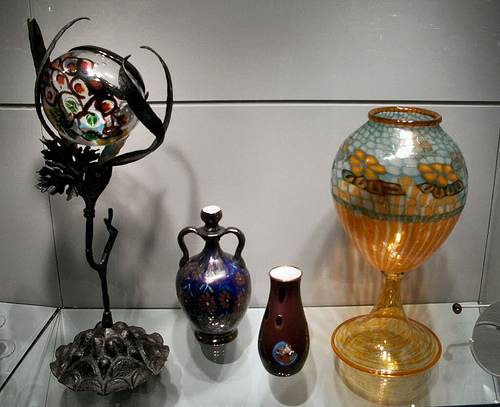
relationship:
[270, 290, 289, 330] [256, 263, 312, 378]
decorative holes in vase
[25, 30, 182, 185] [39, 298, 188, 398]
glass globe on top of art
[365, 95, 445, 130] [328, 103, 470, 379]
opening on top of art piece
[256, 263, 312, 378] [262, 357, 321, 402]
vase has shadow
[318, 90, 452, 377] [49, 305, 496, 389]
glass vase on table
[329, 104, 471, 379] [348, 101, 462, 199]
glass vase has flower decorations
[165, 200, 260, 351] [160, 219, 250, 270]
carafe has handles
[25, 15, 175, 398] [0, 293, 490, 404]
art piece are on table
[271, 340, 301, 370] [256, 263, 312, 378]
decoration on vase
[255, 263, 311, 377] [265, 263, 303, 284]
vase has interior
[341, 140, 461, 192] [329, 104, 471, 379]
flower on glass vase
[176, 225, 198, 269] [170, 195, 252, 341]
handle are on carafe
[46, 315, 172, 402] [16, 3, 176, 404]
base on holder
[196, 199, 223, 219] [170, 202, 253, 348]
lid on carafe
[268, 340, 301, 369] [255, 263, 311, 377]
part adorning vase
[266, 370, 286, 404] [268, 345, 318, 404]
edge lining shadow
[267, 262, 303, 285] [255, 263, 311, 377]
top belonging to vase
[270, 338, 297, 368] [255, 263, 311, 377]
circle painted on vase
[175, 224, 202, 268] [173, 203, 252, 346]
handle attached to vase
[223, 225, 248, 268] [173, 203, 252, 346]
handle attached to vase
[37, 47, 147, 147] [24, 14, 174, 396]
ball mounted on stand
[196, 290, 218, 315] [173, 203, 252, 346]
flower painted on vase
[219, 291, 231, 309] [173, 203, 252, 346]
flower painted on vase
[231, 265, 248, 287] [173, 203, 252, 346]
flower painted on vase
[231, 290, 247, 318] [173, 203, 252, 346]
flower painted on vase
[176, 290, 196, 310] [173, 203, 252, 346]
flower painted on vase